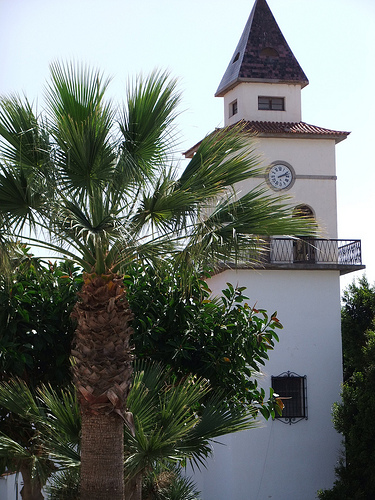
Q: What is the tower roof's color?
A: Brown.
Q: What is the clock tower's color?
A: White.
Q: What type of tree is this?
A: Palm tree.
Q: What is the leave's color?
A: Green.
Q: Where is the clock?
A: On the clock tower.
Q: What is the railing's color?
A: Black.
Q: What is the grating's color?
A: Black.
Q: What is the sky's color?
A: Blue.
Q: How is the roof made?
A: With tiles.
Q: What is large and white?
A: Building.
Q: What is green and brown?
A: Tree.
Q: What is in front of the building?
A: A green leafy tree.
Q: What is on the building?
A: A clock.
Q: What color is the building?
A: White.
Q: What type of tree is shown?
A: A palm tree.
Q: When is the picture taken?
A: Daytime.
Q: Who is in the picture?
A: No one.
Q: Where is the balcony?
A: On the building.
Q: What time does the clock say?
A: 3:06.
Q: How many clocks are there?
A: 1.